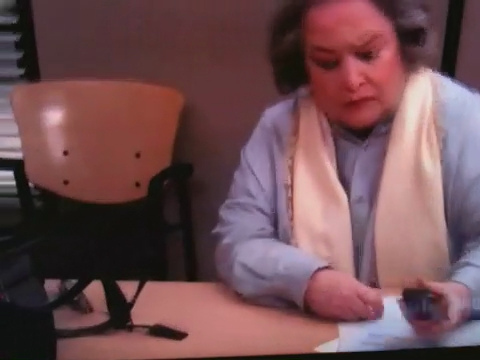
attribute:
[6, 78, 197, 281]
chair — wooden, black, glaring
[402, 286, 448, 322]
phone — black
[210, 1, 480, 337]
woman — female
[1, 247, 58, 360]
bag — black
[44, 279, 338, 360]
table — brown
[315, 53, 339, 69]
eye — closed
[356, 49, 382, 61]
eye — closed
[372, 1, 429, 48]
hair — grey, dark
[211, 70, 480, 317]
shirt — blue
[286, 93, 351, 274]
scarf — white, tan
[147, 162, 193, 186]
arm — black